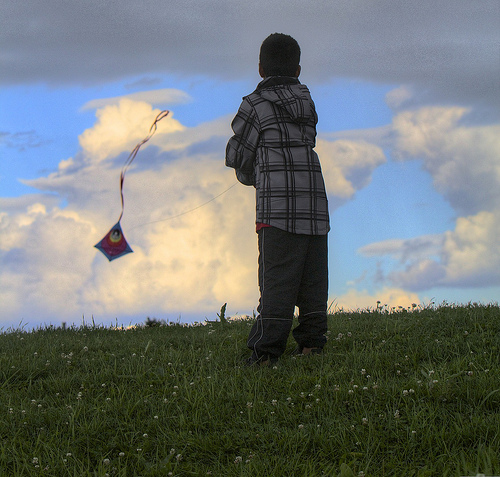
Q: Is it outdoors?
A: Yes, it is outdoors.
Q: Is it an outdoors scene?
A: Yes, it is outdoors.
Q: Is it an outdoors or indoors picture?
A: It is outdoors.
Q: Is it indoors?
A: No, it is outdoors.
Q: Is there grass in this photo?
A: Yes, there is grass.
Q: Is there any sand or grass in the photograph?
A: Yes, there is grass.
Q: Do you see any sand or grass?
A: Yes, there is grass.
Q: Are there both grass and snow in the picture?
A: No, there is grass but no snow.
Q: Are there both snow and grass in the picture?
A: No, there is grass but no snow.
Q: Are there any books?
A: No, there are no books.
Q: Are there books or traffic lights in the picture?
A: No, there are no books or traffic lights.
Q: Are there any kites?
A: Yes, there is a kite.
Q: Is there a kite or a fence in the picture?
A: Yes, there is a kite.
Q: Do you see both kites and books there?
A: No, there is a kite but no books.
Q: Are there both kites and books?
A: No, there is a kite but no books.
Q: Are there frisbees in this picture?
A: No, there are no frisbees.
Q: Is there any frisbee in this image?
A: No, there are no frisbees.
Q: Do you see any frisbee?
A: No, there are no frisbees.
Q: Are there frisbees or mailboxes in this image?
A: No, there are no frisbees or mailboxes.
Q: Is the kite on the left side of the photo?
A: Yes, the kite is on the left of the image.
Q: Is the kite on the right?
A: No, the kite is on the left of the image.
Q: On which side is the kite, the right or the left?
A: The kite is on the left of the image.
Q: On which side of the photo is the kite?
A: The kite is on the left of the image.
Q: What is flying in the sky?
A: The kite is flying in the sky.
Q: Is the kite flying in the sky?
A: Yes, the kite is flying in the sky.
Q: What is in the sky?
A: The kite is in the sky.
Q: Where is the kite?
A: The kite is in the sky.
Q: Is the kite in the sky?
A: Yes, the kite is in the sky.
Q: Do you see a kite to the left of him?
A: Yes, there is a kite to the left of the boy.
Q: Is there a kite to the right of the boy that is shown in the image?
A: No, the kite is to the left of the boy.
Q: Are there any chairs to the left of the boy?
A: No, there is a kite to the left of the boy.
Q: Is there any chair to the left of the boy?
A: No, there is a kite to the left of the boy.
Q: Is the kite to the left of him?
A: Yes, the kite is to the left of a boy.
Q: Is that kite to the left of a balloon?
A: No, the kite is to the left of a boy.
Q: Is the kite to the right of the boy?
A: No, the kite is to the left of the boy.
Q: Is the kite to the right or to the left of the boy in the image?
A: The kite is to the left of the boy.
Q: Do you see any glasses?
A: No, there are no glasses.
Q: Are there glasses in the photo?
A: No, there are no glasses.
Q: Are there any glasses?
A: No, there are no glasses.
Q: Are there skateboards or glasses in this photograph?
A: No, there are no glasses or skateboards.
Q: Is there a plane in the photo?
A: No, there are no airplanes.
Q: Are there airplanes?
A: No, there are no airplanes.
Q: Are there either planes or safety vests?
A: No, there are no planes or safety vests.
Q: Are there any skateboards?
A: No, there are no skateboards.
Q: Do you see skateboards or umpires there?
A: No, there are no skateboards or umpires.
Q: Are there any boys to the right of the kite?
A: Yes, there is a boy to the right of the kite.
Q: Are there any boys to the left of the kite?
A: No, the boy is to the right of the kite.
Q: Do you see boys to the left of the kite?
A: No, the boy is to the right of the kite.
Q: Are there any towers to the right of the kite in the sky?
A: No, there is a boy to the right of the kite.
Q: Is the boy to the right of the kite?
A: Yes, the boy is to the right of the kite.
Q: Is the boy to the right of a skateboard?
A: No, the boy is to the right of the kite.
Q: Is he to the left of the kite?
A: No, the boy is to the right of the kite.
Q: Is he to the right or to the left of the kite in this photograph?
A: The boy is to the right of the kite.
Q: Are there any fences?
A: No, there are no fences.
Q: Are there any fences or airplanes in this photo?
A: No, there are no fences or airplanes.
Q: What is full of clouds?
A: The sky is full of clouds.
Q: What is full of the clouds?
A: The sky is full of clouds.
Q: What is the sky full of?
A: The sky is full of clouds.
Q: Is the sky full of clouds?
A: Yes, the sky is full of clouds.